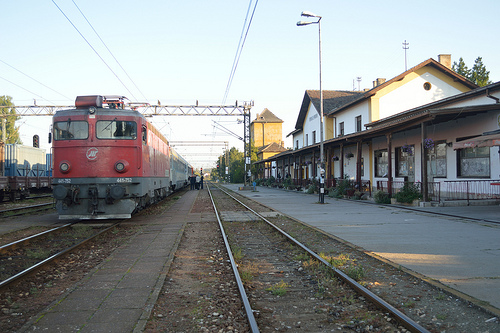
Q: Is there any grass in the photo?
A: Yes, there is grass.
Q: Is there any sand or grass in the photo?
A: Yes, there is grass.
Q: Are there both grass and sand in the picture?
A: No, there is grass but no sand.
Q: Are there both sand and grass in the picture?
A: No, there is grass but no sand.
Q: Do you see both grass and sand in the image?
A: No, there is grass but no sand.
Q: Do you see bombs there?
A: No, there are no bombs.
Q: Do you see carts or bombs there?
A: No, there are no bombs or carts.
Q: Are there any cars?
A: No, there are no cars.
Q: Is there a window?
A: Yes, there is a window.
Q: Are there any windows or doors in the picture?
A: Yes, there is a window.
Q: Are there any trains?
A: Yes, there is a train.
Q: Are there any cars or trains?
A: Yes, there is a train.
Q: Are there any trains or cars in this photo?
A: Yes, there is a train.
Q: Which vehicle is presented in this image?
A: The vehicle is a train.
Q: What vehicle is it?
A: The vehicle is a train.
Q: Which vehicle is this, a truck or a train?
A: That is a train.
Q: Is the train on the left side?
A: Yes, the train is on the left of the image.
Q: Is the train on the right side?
A: No, the train is on the left of the image.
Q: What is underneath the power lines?
A: The train is underneath the power lines.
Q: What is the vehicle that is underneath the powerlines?
A: The vehicle is a train.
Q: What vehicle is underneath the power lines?
A: The vehicle is a train.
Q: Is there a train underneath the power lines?
A: Yes, there is a train underneath the power lines.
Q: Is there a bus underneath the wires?
A: No, there is a train underneath the wires.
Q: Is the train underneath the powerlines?
A: Yes, the train is underneath the powerlines.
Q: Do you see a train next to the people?
A: Yes, there is a train next to the people.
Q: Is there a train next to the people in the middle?
A: Yes, there is a train next to the people.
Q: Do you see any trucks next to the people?
A: No, there is a train next to the people.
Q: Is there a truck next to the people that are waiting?
A: No, there is a train next to the people.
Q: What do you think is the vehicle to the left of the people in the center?
A: The vehicle is a train.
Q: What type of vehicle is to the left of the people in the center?
A: The vehicle is a train.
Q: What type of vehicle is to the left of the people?
A: The vehicle is a train.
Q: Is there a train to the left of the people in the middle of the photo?
A: Yes, there is a train to the left of the people.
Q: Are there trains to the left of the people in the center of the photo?
A: Yes, there is a train to the left of the people.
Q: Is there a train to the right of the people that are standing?
A: No, the train is to the left of the people.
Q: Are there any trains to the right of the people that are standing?
A: No, the train is to the left of the people.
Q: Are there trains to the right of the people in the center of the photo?
A: No, the train is to the left of the people.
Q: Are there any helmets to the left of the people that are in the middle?
A: No, there is a train to the left of the people.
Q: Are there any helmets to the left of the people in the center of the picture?
A: No, there is a train to the left of the people.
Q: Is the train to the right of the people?
A: No, the train is to the left of the people.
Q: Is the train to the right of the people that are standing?
A: No, the train is to the left of the people.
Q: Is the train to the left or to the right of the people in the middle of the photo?
A: The train is to the left of the people.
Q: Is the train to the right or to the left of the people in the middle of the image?
A: The train is to the left of the people.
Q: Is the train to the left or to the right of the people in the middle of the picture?
A: The train is to the left of the people.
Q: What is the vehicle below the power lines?
A: The vehicle is a train.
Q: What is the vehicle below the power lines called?
A: The vehicle is a train.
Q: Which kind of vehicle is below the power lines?
A: The vehicle is a train.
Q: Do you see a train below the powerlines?
A: Yes, there is a train below the powerlines.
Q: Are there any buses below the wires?
A: No, there is a train below the wires.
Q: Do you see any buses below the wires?
A: No, there is a train below the wires.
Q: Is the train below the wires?
A: Yes, the train is below the wires.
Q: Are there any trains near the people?
A: Yes, there is a train near the people.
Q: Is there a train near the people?
A: Yes, there is a train near the people.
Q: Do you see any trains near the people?
A: Yes, there is a train near the people.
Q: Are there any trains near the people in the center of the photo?
A: Yes, there is a train near the people.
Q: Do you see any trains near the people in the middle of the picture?
A: Yes, there is a train near the people.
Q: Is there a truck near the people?
A: No, there is a train near the people.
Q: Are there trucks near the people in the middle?
A: No, there is a train near the people.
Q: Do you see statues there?
A: No, there are no statues.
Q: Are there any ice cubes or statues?
A: No, there are no statues or ice cubes.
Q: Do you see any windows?
A: Yes, there are windows.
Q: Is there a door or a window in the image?
A: Yes, there are windows.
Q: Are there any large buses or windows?
A: Yes, there are large windows.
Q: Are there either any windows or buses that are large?
A: Yes, the windows are large.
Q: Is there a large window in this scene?
A: Yes, there are large windows.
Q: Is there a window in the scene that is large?
A: Yes, there are windows that are large.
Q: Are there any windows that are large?
A: Yes, there are windows that are large.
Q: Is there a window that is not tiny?
A: Yes, there are large windows.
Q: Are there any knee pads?
A: No, there are no knee pads.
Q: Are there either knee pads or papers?
A: No, there are no knee pads or papers.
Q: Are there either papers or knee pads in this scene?
A: No, there are no knee pads or papers.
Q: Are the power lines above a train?
A: Yes, the power lines are above a train.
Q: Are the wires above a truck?
A: No, the wires are above a train.